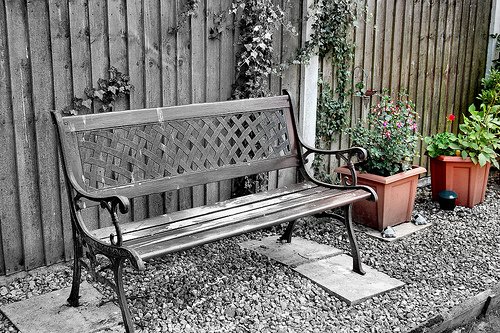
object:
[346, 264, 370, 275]
feet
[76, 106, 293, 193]
lattice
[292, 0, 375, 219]
greenery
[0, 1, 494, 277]
fence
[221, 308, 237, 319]
gravel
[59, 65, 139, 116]
plant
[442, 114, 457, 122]
flowers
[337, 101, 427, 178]
plant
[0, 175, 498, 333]
sidewalk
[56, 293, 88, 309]
feet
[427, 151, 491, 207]
pot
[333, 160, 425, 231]
pot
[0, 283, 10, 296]
rocks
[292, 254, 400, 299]
cement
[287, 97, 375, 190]
arm rail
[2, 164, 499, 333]
ground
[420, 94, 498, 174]
plant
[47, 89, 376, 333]
bench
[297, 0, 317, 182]
post